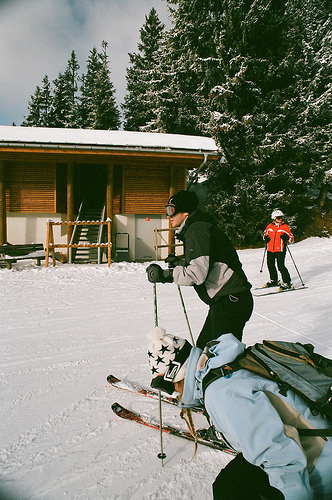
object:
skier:
[145, 327, 331, 500]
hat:
[144, 325, 193, 387]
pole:
[283, 242, 306, 290]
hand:
[279, 233, 289, 243]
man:
[145, 189, 255, 444]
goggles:
[164, 202, 178, 217]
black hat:
[166, 189, 199, 214]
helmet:
[270, 206, 282, 225]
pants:
[192, 289, 253, 350]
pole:
[178, 287, 196, 349]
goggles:
[150, 375, 176, 395]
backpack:
[202, 338, 332, 437]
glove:
[144, 262, 174, 284]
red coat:
[262, 219, 293, 254]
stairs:
[73, 256, 98, 267]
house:
[0, 123, 224, 263]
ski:
[109, 402, 237, 459]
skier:
[260, 209, 293, 293]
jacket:
[171, 210, 252, 306]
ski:
[250, 283, 308, 298]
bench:
[45, 216, 113, 271]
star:
[158, 344, 171, 354]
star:
[153, 354, 163, 366]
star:
[170, 334, 179, 344]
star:
[149, 365, 158, 377]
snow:
[0, 236, 331, 500]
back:
[216, 349, 328, 426]